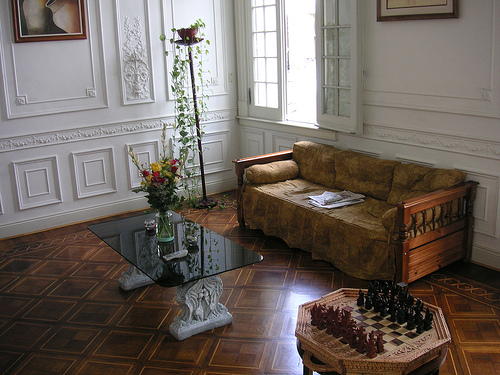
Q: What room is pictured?
A: It is a living room.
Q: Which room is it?
A: It is a living room.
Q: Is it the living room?
A: Yes, it is the living room.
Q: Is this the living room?
A: Yes, it is the living room.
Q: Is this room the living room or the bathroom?
A: It is the living room.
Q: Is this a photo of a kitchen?
A: No, the picture is showing a living room.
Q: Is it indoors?
A: Yes, it is indoors.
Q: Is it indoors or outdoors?
A: It is indoors.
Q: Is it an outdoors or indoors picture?
A: It is indoors.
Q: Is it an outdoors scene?
A: No, it is indoors.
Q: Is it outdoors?
A: No, it is indoors.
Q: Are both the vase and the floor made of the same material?
A: No, the vase is made of glass and the floor is made of wood.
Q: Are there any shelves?
A: No, there are no shelves.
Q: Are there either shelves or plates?
A: No, there are no shelves or plates.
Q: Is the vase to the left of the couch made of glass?
A: Yes, the vase is made of glass.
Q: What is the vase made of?
A: The vase is made of glass.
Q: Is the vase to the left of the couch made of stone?
A: No, the vase is made of glass.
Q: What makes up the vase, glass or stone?
A: The vase is made of glass.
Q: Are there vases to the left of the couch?
A: Yes, there is a vase to the left of the couch.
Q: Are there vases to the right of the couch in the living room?
A: No, the vase is to the left of the couch.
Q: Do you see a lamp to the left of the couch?
A: No, there is a vase to the left of the couch.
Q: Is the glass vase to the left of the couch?
A: Yes, the vase is to the left of the couch.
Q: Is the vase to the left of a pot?
A: No, the vase is to the left of the couch.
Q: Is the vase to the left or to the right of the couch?
A: The vase is to the left of the couch.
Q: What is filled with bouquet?
A: The vase is filled with bouquet.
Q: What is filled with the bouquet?
A: The vase is filled with bouquet.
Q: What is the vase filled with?
A: The vase is filled with bouquet.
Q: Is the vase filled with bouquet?
A: Yes, the vase is filled with bouquet.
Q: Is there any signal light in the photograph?
A: No, there are no traffic lights.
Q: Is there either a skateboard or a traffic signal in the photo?
A: No, there are no traffic lights or skateboards.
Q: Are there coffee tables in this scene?
A: Yes, there is a coffee table.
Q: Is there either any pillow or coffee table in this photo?
A: Yes, there is a coffee table.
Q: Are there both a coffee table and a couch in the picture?
A: Yes, there are both a coffee table and a couch.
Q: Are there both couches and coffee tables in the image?
A: Yes, there are both a coffee table and a couch.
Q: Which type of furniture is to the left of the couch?
A: The piece of furniture is a coffee table.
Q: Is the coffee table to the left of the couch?
A: Yes, the coffee table is to the left of the couch.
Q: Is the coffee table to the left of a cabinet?
A: No, the coffee table is to the left of the couch.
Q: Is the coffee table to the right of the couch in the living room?
A: No, the coffee table is to the left of the couch.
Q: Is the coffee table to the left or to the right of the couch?
A: The coffee table is to the left of the couch.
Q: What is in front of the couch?
A: The coffee table is in front of the couch.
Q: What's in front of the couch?
A: The coffee table is in front of the couch.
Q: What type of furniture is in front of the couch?
A: The piece of furniture is a coffee table.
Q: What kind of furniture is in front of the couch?
A: The piece of furniture is a coffee table.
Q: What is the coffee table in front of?
A: The coffee table is in front of the couch.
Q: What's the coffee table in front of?
A: The coffee table is in front of the couch.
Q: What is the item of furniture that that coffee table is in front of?
A: The piece of furniture is a couch.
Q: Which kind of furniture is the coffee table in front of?
A: The coffee table is in front of the couch.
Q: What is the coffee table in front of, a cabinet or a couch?
A: The coffee table is in front of a couch.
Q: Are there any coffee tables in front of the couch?
A: Yes, there is a coffee table in front of the couch.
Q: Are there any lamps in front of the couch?
A: No, there is a coffee table in front of the couch.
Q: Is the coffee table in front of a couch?
A: Yes, the coffee table is in front of a couch.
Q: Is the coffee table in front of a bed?
A: No, the coffee table is in front of a couch.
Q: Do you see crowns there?
A: No, there are no crowns.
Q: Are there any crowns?
A: No, there are no crowns.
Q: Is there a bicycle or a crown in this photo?
A: No, there are no crowns or bicycles.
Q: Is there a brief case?
A: No, there are no briefcases.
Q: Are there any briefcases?
A: No, there are no briefcases.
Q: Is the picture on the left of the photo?
A: Yes, the picture is on the left of the image.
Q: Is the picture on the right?
A: No, the picture is on the left of the image.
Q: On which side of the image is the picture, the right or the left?
A: The picture is on the left of the image.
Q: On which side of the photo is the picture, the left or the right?
A: The picture is on the left of the image.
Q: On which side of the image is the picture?
A: The picture is on the left of the image.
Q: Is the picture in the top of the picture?
A: Yes, the picture is in the top of the image.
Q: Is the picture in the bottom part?
A: No, the picture is in the top of the image.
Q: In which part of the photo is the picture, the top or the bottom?
A: The picture is in the top of the image.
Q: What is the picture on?
A: The picture is on the wall.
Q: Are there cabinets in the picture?
A: No, there are no cabinets.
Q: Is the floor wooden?
A: Yes, the floor is wooden.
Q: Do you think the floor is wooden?
A: Yes, the floor is wooden.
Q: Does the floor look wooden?
A: Yes, the floor is wooden.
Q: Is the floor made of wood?
A: Yes, the floor is made of wood.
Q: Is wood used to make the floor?
A: Yes, the floor is made of wood.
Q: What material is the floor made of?
A: The floor is made of wood.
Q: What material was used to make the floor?
A: The floor is made of wood.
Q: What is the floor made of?
A: The floor is made of wood.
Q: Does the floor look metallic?
A: No, the floor is wooden.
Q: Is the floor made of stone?
A: No, the floor is made of wood.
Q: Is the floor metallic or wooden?
A: The floor is wooden.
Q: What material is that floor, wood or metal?
A: The floor is made of wood.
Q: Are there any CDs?
A: No, there are no cds.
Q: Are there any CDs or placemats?
A: No, there are no CDs or placemats.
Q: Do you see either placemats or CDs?
A: No, there are no CDs or placemats.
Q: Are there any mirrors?
A: No, there are no mirrors.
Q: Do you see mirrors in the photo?
A: No, there are no mirrors.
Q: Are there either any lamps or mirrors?
A: No, there are no mirrors or lamps.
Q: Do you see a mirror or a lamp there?
A: No, there are no mirrors or lamps.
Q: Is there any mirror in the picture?
A: No, there are no mirrors.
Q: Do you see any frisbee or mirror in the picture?
A: No, there are no mirrors or frisbees.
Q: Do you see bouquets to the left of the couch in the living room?
A: Yes, there is a bouquet to the left of the couch.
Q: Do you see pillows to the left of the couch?
A: No, there is a bouquet to the left of the couch.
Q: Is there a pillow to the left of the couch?
A: No, there is a bouquet to the left of the couch.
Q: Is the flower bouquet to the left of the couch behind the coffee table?
A: Yes, the flower bouquet is to the left of the couch.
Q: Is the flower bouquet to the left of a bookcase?
A: No, the flower bouquet is to the left of the couch.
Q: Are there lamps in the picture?
A: No, there are no lamps.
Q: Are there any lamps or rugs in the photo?
A: No, there are no lamps or rugs.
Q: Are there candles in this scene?
A: No, there are no candles.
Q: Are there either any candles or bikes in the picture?
A: No, there are no candles or bikes.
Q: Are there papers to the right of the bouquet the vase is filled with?
A: Yes, there are papers to the right of the bouquet.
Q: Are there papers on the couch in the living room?
A: Yes, there are papers on the couch.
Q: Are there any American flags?
A: No, there are no American flags.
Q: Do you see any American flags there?
A: No, there are no American flags.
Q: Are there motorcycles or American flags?
A: No, there are no American flags or motorcycles.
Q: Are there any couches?
A: Yes, there is a couch.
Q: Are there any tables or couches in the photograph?
A: Yes, there is a couch.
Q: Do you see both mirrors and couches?
A: No, there is a couch but no mirrors.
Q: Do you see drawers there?
A: No, there are no drawers.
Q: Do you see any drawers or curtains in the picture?
A: No, there are no drawers or curtains.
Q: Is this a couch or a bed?
A: This is a couch.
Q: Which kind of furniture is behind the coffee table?
A: The piece of furniture is a couch.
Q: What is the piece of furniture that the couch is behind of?
A: The piece of furniture is a coffee table.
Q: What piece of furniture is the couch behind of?
A: The couch is behind the coffee table.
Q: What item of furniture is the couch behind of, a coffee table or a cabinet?
A: The couch is behind a coffee table.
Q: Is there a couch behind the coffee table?
A: Yes, there is a couch behind the coffee table.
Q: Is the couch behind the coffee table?
A: Yes, the couch is behind the coffee table.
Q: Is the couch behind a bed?
A: No, the couch is behind the coffee table.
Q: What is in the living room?
A: The couch is in the living room.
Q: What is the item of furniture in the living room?
A: The piece of furniture is a couch.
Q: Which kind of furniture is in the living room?
A: The piece of furniture is a couch.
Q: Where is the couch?
A: The couch is in the living room.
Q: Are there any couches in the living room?
A: Yes, there is a couch in the living room.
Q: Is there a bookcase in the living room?
A: No, there is a couch in the living room.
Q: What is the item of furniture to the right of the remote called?
A: The piece of furniture is a couch.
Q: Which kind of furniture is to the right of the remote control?
A: The piece of furniture is a couch.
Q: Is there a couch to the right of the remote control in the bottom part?
A: Yes, there is a couch to the right of the remote control.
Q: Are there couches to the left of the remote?
A: No, the couch is to the right of the remote.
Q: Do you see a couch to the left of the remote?
A: No, the couch is to the right of the remote.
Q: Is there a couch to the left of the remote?
A: No, the couch is to the right of the remote.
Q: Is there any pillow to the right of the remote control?
A: No, there is a couch to the right of the remote control.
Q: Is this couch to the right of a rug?
A: No, the couch is to the right of the remote.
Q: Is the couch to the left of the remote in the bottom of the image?
A: No, the couch is to the right of the remote control.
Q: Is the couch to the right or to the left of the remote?
A: The couch is to the right of the remote.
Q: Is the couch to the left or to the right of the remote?
A: The couch is to the right of the remote.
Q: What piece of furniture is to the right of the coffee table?
A: The piece of furniture is a couch.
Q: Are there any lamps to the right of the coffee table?
A: No, there is a couch to the right of the coffee table.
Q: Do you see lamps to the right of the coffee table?
A: No, there is a couch to the right of the coffee table.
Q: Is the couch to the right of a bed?
A: No, the couch is to the right of the coffee table.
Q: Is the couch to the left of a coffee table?
A: No, the couch is to the right of a coffee table.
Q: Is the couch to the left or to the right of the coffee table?
A: The couch is to the right of the coffee table.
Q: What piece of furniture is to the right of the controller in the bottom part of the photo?
A: The piece of furniture is a couch.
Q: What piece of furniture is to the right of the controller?
A: The piece of furniture is a couch.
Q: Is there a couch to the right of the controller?
A: Yes, there is a couch to the right of the controller.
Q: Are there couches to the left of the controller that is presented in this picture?
A: No, the couch is to the right of the controller.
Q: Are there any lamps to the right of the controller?
A: No, there is a couch to the right of the controller.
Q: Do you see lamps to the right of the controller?
A: No, there is a couch to the right of the controller.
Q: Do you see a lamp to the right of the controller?
A: No, there is a couch to the right of the controller.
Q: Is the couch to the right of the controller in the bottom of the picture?
A: Yes, the couch is to the right of the controller.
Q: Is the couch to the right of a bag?
A: No, the couch is to the right of the controller.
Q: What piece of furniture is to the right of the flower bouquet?
A: The piece of furniture is a couch.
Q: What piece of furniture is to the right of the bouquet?
A: The piece of furniture is a couch.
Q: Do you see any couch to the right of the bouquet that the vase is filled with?
A: Yes, there is a couch to the right of the flower bouquet.